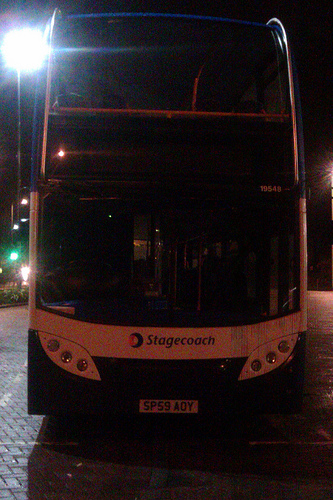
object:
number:
[260, 183, 263, 191]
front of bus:
[45, 8, 300, 431]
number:
[271, 183, 276, 193]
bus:
[20, 8, 304, 443]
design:
[122, 324, 223, 356]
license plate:
[135, 386, 199, 415]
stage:
[143, 328, 181, 350]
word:
[177, 332, 189, 352]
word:
[203, 333, 218, 352]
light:
[3, 25, 52, 76]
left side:
[1, 3, 201, 499]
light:
[3, 245, 23, 265]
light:
[15, 265, 38, 287]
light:
[275, 334, 294, 355]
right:
[165, 5, 327, 500]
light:
[264, 348, 280, 366]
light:
[248, 355, 262, 372]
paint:
[29, 332, 307, 413]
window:
[46, 26, 293, 112]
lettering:
[138, 392, 195, 413]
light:
[58, 350, 73, 365]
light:
[44, 333, 60, 353]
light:
[75, 354, 91, 374]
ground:
[3, 311, 329, 495]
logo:
[121, 327, 222, 350]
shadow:
[27, 418, 331, 500]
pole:
[7, 43, 36, 254]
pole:
[193, 209, 214, 314]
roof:
[45, 8, 292, 39]